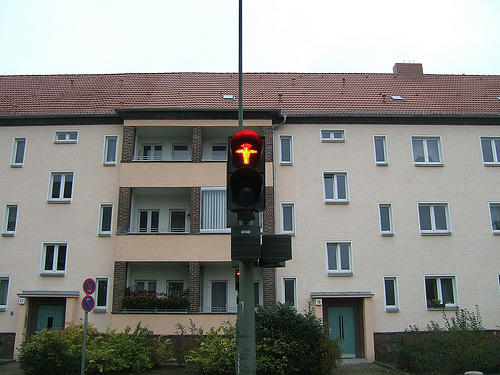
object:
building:
[0, 67, 497, 366]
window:
[423, 274, 463, 311]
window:
[324, 236, 358, 276]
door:
[324, 305, 358, 362]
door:
[34, 302, 66, 362]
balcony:
[118, 122, 278, 188]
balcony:
[111, 188, 280, 264]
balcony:
[108, 261, 283, 335]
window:
[323, 169, 351, 206]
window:
[418, 203, 455, 239]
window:
[411, 134, 445, 169]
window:
[45, 168, 76, 204]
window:
[39, 239, 70, 276]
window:
[480, 134, 499, 170]